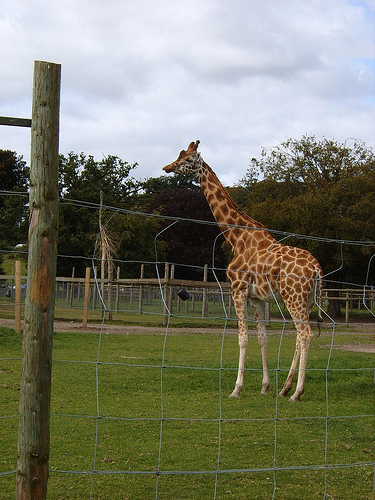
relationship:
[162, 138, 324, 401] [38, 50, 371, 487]
giraffe standing in enclosure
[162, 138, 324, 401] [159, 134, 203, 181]
giraffe has head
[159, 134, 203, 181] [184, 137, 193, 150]
head has horn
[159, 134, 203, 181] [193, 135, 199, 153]
head has horn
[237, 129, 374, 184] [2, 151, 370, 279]
tree sticking out treeline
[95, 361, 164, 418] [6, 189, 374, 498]
gaps in fence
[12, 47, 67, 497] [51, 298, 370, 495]
post in foreground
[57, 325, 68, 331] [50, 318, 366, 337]
dirt on path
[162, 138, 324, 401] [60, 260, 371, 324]
giraffe in fencing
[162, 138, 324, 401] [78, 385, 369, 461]
giraffe in grass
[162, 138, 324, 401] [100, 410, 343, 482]
giraffe in grass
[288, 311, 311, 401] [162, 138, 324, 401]
leg on giraffe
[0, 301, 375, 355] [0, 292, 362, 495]
dirt covering surface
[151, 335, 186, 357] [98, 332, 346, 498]
grass covering ground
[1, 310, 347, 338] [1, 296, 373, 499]
dirt on ground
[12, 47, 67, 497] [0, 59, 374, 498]
post on fence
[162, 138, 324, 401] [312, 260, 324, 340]
giraffe has tail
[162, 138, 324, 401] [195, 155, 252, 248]
giraffe has mane